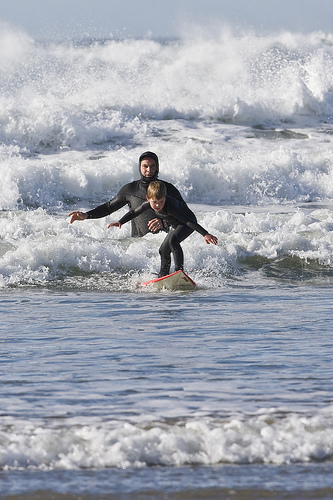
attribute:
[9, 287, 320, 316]
water — calm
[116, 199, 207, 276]
wetsuit — black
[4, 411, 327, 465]
foam — white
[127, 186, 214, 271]
boy — young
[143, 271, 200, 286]
surfboard — white, red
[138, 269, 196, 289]
surfboard — white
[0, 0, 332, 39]
sky — blue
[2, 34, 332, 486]
water — white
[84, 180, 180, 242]
wetsuit — black